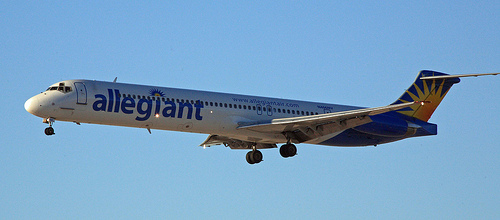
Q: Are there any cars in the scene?
A: No, there are no cars.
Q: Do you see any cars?
A: No, there are no cars.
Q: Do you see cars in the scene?
A: No, there are no cars.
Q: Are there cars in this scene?
A: No, there are no cars.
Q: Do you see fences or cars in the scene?
A: No, there are no cars or fences.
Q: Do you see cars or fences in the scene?
A: No, there are no cars or fences.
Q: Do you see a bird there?
A: No, there are no birds.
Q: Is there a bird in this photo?
A: No, there are no birds.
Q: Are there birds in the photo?
A: No, there are no birds.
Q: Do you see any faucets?
A: No, there are no faucets.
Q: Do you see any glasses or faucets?
A: No, there are no faucets or glasses.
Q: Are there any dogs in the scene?
A: No, there are no dogs.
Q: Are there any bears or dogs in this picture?
A: No, there are no dogs or bears.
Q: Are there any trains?
A: No, there are no trains.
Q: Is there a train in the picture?
A: No, there are no trains.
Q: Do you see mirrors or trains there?
A: No, there are no trains or mirrors.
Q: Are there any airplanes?
A: Yes, there is an airplane.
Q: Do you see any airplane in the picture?
A: Yes, there is an airplane.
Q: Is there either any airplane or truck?
A: Yes, there is an airplane.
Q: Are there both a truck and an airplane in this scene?
A: No, there is an airplane but no trucks.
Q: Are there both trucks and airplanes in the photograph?
A: No, there is an airplane but no trucks.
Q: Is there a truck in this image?
A: No, there are no trucks.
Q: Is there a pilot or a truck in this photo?
A: No, there are no trucks or pilots.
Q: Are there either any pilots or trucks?
A: No, there are no trucks or pilots.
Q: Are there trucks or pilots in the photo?
A: No, there are no trucks or pilots.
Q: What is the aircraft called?
A: The aircraft is an airplane.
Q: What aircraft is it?
A: The aircraft is an airplane.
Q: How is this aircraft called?
A: This is an airplane.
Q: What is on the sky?
A: The airplane is on the sky.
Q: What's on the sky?
A: The airplane is on the sky.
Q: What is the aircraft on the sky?
A: The aircraft is an airplane.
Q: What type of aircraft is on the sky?
A: The aircraft is an airplane.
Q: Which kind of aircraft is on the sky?
A: The aircraft is an airplane.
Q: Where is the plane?
A: The plane is on the sky.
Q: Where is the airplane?
A: The plane is on the sky.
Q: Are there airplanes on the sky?
A: Yes, there is an airplane on the sky.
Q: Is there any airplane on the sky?
A: Yes, there is an airplane on the sky.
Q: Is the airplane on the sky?
A: Yes, the airplane is on the sky.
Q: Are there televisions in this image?
A: No, there are no televisions.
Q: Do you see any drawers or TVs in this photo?
A: No, there are no TVs or drawers.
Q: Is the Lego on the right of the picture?
A: Yes, the Lego is on the right of the image.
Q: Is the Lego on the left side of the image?
A: No, the Lego is on the right of the image.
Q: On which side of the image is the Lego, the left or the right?
A: The Lego is on the right of the image.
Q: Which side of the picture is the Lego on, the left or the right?
A: The Lego is on the right of the image.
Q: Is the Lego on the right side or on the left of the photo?
A: The Lego is on the right of the image.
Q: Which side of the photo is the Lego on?
A: The Lego is on the right of the image.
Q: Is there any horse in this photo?
A: No, there are no horses.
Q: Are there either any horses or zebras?
A: No, there are no horses or zebras.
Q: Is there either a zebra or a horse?
A: No, there are no horses or zebras.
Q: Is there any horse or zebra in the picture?
A: No, there are no horses or zebras.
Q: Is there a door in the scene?
A: Yes, there is a door.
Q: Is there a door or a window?
A: Yes, there is a door.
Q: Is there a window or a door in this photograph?
A: Yes, there is a door.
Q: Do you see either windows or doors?
A: Yes, there is a door.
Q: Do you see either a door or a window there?
A: Yes, there is a door.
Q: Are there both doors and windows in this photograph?
A: Yes, there are both a door and a window.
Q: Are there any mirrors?
A: No, there are no mirrors.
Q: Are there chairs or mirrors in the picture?
A: No, there are no mirrors or chairs.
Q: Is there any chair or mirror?
A: No, there are no mirrors or chairs.